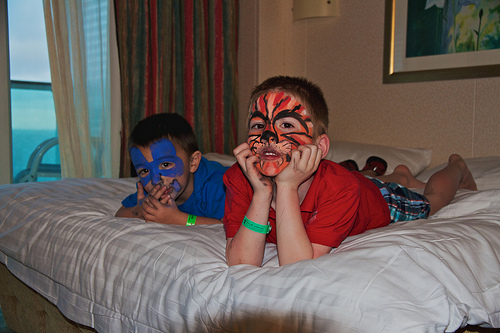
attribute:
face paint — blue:
[133, 143, 191, 201]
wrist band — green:
[178, 212, 199, 227]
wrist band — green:
[239, 214, 274, 237]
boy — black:
[247, 87, 331, 195]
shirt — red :
[203, 155, 402, 260]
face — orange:
[241, 85, 317, 185]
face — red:
[242, 83, 322, 182]